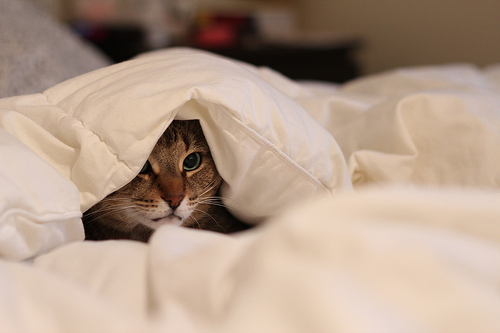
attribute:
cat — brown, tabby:
[67, 114, 242, 239]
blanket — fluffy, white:
[25, 59, 463, 226]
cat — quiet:
[85, 105, 255, 250]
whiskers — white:
[65, 182, 250, 234]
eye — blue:
[177, 146, 204, 180]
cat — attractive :
[49, 87, 284, 258]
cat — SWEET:
[116, 114, 219, 231]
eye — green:
[183, 151, 201, 170]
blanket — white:
[1, 31, 498, 330]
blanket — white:
[257, 101, 443, 284]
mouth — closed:
[112, 160, 247, 245]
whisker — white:
[83, 202, 136, 217]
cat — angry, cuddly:
[81, 113, 245, 246]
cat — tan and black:
[129, 121, 214, 231]